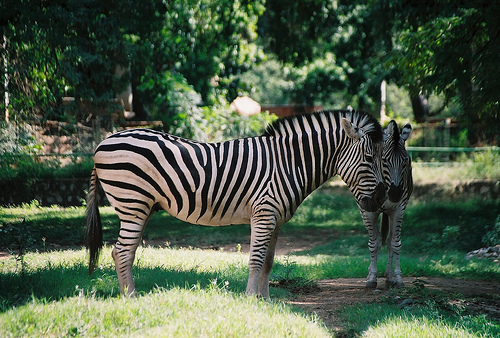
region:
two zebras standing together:
[72, 93, 412, 292]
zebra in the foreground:
[79, 101, 391, 301]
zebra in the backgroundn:
[360, 120, 415, 282]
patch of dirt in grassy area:
[302, 236, 497, 323]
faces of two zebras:
[335, 106, 414, 212]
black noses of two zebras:
[352, 184, 404, 214]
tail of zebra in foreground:
[77, 165, 112, 277]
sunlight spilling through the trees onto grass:
[17, 183, 321, 336]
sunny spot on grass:
[29, 279, 405, 336]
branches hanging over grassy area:
[15, 6, 490, 125]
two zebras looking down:
[70, 98, 429, 298]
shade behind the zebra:
[0, 261, 73, 310]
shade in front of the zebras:
[294, 288, 497, 331]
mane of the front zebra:
[257, 107, 383, 140]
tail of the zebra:
[82, 155, 100, 287]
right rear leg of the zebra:
[98, 190, 160, 323]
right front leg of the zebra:
[227, 196, 287, 308]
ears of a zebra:
[370, 119, 420, 147]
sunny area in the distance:
[415, 153, 495, 188]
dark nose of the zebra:
[357, 179, 389, 214]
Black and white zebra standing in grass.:
[85, 108, 386, 298]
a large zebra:
[77, 115, 379, 301]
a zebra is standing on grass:
[1, 295, 373, 337]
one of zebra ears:
[341, 117, 358, 139]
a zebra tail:
[82, 165, 104, 275]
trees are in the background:
[2, 2, 497, 109]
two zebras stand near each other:
[72, 113, 415, 303]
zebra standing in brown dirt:
[324, 275, 497, 305]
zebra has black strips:
[96, 143, 288, 221]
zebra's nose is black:
[361, 185, 386, 205]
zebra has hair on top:
[261, 107, 384, 135]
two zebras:
[349, 116, 422, 221]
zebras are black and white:
[205, 154, 290, 201]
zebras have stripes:
[161, 139, 272, 197]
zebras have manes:
[303, 98, 337, 115]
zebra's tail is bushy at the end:
[89, 210, 93, 255]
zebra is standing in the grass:
[240, 285, 285, 330]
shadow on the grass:
[121, 241, 196, 297]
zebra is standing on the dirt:
[355, 279, 396, 295]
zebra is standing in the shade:
[387, 152, 409, 210]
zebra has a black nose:
[367, 194, 378, 205]